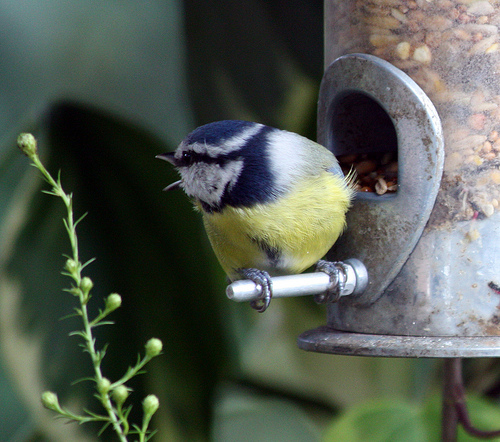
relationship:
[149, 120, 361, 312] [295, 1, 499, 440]
bird near a feeder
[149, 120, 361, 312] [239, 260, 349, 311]
bird has feet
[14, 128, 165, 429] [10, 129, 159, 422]
plant has buds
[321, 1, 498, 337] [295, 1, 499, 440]
grains are in feeder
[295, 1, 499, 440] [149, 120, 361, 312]
feeder in front of bird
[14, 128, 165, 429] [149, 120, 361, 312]
plant in front of bird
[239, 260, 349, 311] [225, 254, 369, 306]
feet are around a rod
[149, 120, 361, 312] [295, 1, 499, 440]
bird on feeder